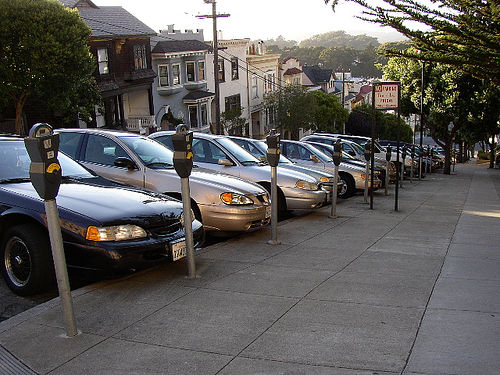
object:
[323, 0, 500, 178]
trees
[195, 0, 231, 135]
pole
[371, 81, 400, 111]
parking sign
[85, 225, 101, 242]
turn signal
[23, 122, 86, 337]
meter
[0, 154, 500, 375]
ground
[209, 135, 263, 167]
windshield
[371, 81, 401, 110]
signboard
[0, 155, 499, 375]
sidewalk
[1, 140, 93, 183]
window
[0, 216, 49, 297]
front tire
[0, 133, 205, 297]
black car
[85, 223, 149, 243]
headlight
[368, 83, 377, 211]
pole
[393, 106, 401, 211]
pole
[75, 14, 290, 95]
wire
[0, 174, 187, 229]
hood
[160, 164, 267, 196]
hood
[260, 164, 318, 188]
hood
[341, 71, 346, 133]
pole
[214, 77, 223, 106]
wood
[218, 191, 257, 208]
headlight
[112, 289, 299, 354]
square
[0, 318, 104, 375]
square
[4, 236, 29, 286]
hubcap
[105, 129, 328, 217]
car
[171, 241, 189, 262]
plate